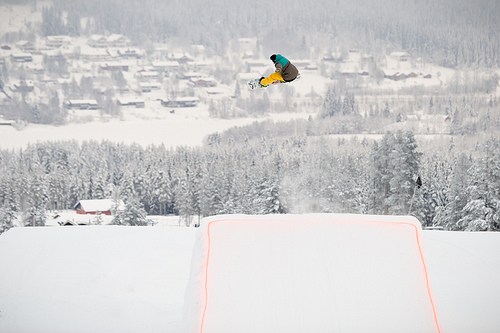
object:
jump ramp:
[193, 211, 450, 333]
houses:
[116, 96, 146, 108]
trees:
[1, 2, 500, 66]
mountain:
[0, 140, 497, 330]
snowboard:
[247, 77, 267, 90]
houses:
[100, 62, 130, 72]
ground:
[310, 114, 456, 140]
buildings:
[160, 96, 199, 107]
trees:
[0, 137, 83, 227]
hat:
[269, 53, 277, 63]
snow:
[253, 233, 368, 311]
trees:
[437, 144, 500, 229]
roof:
[74, 199, 126, 212]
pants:
[259, 73, 285, 87]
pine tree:
[389, 121, 425, 213]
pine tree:
[363, 140, 388, 214]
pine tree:
[326, 141, 359, 213]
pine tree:
[295, 152, 332, 211]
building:
[73, 199, 125, 216]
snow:
[81, 196, 111, 207]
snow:
[41, 226, 161, 321]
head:
[269, 54, 277, 62]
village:
[0, 33, 500, 163]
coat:
[259, 54, 298, 87]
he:
[256, 53, 298, 89]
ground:
[0, 212, 500, 330]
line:
[413, 225, 440, 332]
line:
[206, 217, 415, 226]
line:
[197, 218, 218, 332]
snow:
[4, 0, 201, 148]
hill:
[0, 0, 500, 127]